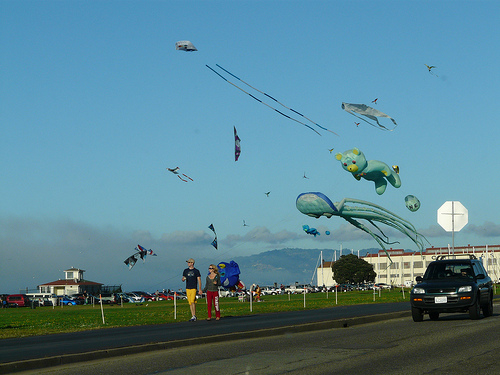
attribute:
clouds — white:
[3, 206, 483, 237]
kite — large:
[175, 39, 337, 136]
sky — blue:
[2, 0, 496, 292]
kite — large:
[231, 161, 418, 253]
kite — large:
[334, 145, 408, 196]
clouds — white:
[65, 183, 140, 234]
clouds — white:
[3, 219, 497, 291]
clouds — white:
[0, 207, 499, 291]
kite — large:
[328, 143, 408, 199]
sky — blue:
[2, 3, 482, 246]